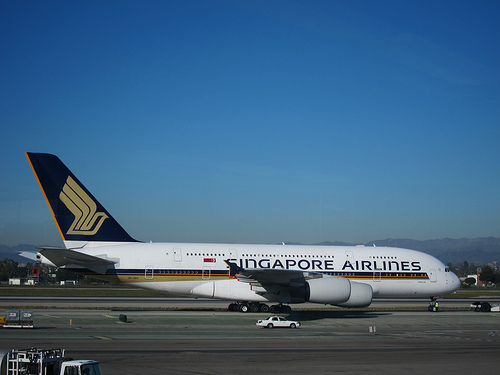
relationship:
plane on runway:
[19, 151, 460, 315] [2, 291, 500, 371]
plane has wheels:
[19, 151, 460, 315] [227, 300, 437, 315]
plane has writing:
[19, 151, 460, 315] [223, 256, 423, 274]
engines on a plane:
[298, 278, 372, 310] [19, 151, 460, 315]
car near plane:
[256, 317, 301, 330] [19, 151, 460, 315]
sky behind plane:
[2, 1, 500, 259] [19, 151, 460, 315]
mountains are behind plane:
[354, 235, 500, 270] [19, 151, 460, 315]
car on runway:
[256, 317, 301, 330] [2, 291, 500, 371]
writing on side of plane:
[223, 256, 423, 274] [19, 151, 460, 315]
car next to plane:
[256, 317, 301, 330] [19, 151, 460, 315]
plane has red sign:
[19, 151, 460, 315] [203, 256, 217, 263]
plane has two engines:
[19, 151, 460, 315] [298, 278, 372, 310]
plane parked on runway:
[19, 151, 460, 315] [2, 291, 500, 371]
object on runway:
[368, 327, 378, 335] [2, 291, 500, 371]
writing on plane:
[223, 256, 423, 274] [19, 151, 460, 315]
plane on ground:
[19, 151, 460, 315] [1, 281, 499, 374]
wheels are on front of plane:
[227, 300, 437, 315] [19, 151, 460, 315]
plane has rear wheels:
[19, 151, 460, 315] [227, 300, 437, 315]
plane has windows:
[19, 151, 460, 315] [185, 251, 402, 260]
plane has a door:
[19, 151, 460, 315] [200, 263, 211, 281]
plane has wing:
[19, 151, 460, 315] [225, 262, 372, 308]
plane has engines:
[19, 151, 460, 315] [298, 278, 372, 310]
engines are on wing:
[298, 278, 372, 310] [225, 262, 372, 308]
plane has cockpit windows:
[19, 151, 460, 315] [443, 266, 453, 274]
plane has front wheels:
[19, 151, 460, 315] [227, 300, 437, 315]